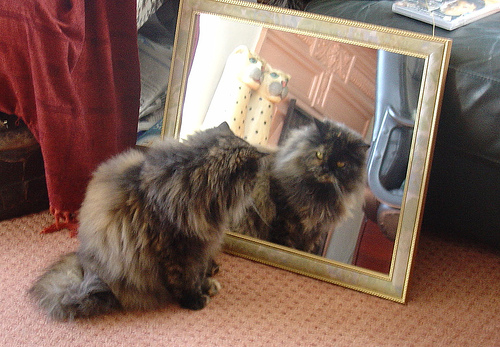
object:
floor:
[0, 214, 499, 344]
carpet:
[1, 209, 500, 346]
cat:
[24, 121, 271, 323]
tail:
[19, 253, 124, 325]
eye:
[311, 148, 328, 164]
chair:
[364, 49, 424, 209]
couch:
[295, 2, 498, 257]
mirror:
[175, 14, 425, 281]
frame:
[158, 1, 452, 304]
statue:
[200, 44, 268, 139]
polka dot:
[243, 95, 246, 99]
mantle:
[253, 23, 378, 266]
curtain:
[2, 3, 140, 237]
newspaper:
[137, 32, 171, 133]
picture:
[389, 0, 500, 33]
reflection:
[234, 116, 372, 252]